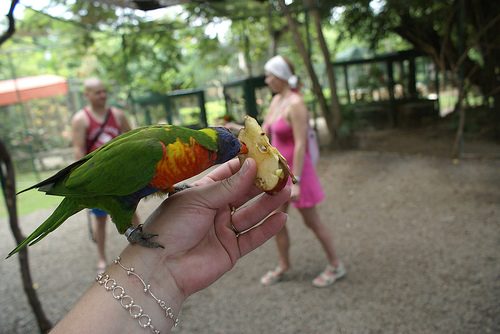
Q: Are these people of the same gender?
A: No, they are both male and female.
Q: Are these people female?
A: No, they are both male and female.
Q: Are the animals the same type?
A: No, they are birds and parrots.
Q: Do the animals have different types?
A: Yes, they are birds and parrots.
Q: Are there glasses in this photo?
A: No, there are no glasses.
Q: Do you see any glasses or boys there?
A: No, there are no glasses or boys.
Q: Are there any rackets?
A: No, there are no rackets.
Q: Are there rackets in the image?
A: No, there are no rackets.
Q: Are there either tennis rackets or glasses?
A: No, there are no tennis rackets or glasses.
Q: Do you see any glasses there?
A: No, there are no glasses.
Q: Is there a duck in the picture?
A: No, there are no ducks.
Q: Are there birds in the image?
A: Yes, there is a bird.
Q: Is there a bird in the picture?
A: Yes, there is a bird.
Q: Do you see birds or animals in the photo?
A: Yes, there is a bird.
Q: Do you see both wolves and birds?
A: No, there is a bird but no wolves.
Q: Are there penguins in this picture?
A: No, there are no penguins.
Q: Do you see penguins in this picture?
A: No, there are no penguins.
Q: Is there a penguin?
A: No, there are no penguins.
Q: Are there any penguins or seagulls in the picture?
A: No, there are no penguins or seagulls.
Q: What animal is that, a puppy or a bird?
A: That is a bird.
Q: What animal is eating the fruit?
A: The bird is eating the fruit.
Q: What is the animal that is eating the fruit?
A: The animal is a bird.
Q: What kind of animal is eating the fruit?
A: The animal is a bird.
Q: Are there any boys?
A: No, there are no boys.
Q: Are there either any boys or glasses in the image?
A: No, there are no boys or glasses.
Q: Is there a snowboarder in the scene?
A: No, there are no snowboarders.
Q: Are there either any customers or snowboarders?
A: No, there are no snowboarders or customers.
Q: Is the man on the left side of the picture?
A: Yes, the man is on the left of the image.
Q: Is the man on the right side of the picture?
A: No, the man is on the left of the image.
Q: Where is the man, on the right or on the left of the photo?
A: The man is on the left of the image.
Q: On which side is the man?
A: The man is on the left of the image.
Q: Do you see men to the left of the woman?
A: Yes, there is a man to the left of the woman.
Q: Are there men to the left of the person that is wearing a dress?
A: Yes, there is a man to the left of the woman.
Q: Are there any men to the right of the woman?
A: No, the man is to the left of the woman.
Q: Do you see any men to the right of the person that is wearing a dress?
A: No, the man is to the left of the woman.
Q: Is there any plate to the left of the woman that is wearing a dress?
A: No, there is a man to the left of the woman.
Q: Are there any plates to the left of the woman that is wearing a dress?
A: No, there is a man to the left of the woman.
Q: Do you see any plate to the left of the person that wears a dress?
A: No, there is a man to the left of the woman.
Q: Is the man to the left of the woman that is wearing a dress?
A: Yes, the man is to the left of the woman.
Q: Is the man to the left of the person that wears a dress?
A: Yes, the man is to the left of the woman.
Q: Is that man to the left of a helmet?
A: No, the man is to the left of the woman.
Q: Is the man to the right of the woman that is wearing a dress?
A: No, the man is to the left of the woman.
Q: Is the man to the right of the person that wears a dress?
A: No, the man is to the left of the woman.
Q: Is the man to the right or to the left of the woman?
A: The man is to the left of the woman.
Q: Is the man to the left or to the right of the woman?
A: The man is to the left of the woman.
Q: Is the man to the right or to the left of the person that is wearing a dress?
A: The man is to the left of the woman.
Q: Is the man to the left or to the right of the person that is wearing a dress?
A: The man is to the left of the woman.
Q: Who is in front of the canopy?
A: The man is in front of the canopy.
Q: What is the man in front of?
A: The man is in front of the canopy.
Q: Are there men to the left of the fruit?
A: Yes, there is a man to the left of the fruit.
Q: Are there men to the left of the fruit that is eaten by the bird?
A: Yes, there is a man to the left of the fruit.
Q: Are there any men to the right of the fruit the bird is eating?
A: No, the man is to the left of the fruit.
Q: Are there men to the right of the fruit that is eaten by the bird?
A: No, the man is to the left of the fruit.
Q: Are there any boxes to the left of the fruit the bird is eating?
A: No, there is a man to the left of the fruit.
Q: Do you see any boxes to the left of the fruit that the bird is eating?
A: No, there is a man to the left of the fruit.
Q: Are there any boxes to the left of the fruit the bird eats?
A: No, there is a man to the left of the fruit.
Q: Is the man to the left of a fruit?
A: Yes, the man is to the left of a fruit.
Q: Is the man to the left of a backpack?
A: No, the man is to the left of a fruit.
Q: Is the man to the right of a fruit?
A: No, the man is to the left of a fruit.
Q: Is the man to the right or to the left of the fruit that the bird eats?
A: The man is to the left of the fruit.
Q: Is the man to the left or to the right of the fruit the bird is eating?
A: The man is to the left of the fruit.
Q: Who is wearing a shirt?
A: The man is wearing a shirt.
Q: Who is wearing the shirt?
A: The man is wearing a shirt.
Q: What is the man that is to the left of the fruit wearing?
A: The man is wearing a shirt.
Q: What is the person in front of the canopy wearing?
A: The man is wearing a shirt.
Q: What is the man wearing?
A: The man is wearing a shirt.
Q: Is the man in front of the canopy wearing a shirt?
A: Yes, the man is wearing a shirt.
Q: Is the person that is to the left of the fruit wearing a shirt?
A: Yes, the man is wearing a shirt.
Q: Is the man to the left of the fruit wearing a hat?
A: No, the man is wearing a shirt.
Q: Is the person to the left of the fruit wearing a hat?
A: No, the man is wearing a shirt.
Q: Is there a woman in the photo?
A: Yes, there is a woman.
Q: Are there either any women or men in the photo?
A: Yes, there is a woman.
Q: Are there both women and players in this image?
A: No, there is a woman but no players.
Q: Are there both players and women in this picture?
A: No, there is a woman but no players.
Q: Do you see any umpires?
A: No, there are no umpires.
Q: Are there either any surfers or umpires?
A: No, there are no umpires or surfers.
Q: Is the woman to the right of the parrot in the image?
A: Yes, the woman is to the right of the parrot.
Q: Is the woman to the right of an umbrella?
A: No, the woman is to the right of the parrot.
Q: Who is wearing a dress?
A: The woman is wearing a dress.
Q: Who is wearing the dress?
A: The woman is wearing a dress.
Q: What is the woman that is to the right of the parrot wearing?
A: The woman is wearing a dress.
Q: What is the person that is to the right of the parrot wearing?
A: The woman is wearing a dress.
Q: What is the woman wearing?
A: The woman is wearing a dress.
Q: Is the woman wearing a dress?
A: Yes, the woman is wearing a dress.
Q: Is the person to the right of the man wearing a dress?
A: Yes, the woman is wearing a dress.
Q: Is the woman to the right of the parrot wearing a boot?
A: No, the woman is wearing a dress.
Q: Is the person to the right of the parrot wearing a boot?
A: No, the woman is wearing a dress.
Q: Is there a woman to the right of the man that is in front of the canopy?
A: Yes, there is a woman to the right of the man.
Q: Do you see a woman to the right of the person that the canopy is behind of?
A: Yes, there is a woman to the right of the man.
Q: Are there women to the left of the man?
A: No, the woman is to the right of the man.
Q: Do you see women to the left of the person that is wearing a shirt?
A: No, the woman is to the right of the man.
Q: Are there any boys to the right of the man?
A: No, there is a woman to the right of the man.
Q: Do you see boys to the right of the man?
A: No, there is a woman to the right of the man.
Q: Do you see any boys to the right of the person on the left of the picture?
A: No, there is a woman to the right of the man.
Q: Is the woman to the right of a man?
A: Yes, the woman is to the right of a man.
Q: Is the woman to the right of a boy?
A: No, the woman is to the right of a man.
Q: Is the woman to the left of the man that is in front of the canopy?
A: No, the woman is to the right of the man.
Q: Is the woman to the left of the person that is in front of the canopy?
A: No, the woman is to the right of the man.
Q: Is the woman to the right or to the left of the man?
A: The woman is to the right of the man.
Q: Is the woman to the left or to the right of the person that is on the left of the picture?
A: The woman is to the right of the man.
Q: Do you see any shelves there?
A: No, there are no shelves.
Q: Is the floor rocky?
A: Yes, the floor is rocky.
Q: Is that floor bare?
A: No, the floor is rocky.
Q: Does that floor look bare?
A: No, the floor is rocky.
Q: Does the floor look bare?
A: No, the floor is rocky.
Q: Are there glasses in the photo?
A: No, there are no glasses.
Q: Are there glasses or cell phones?
A: No, there are no glasses or cell phones.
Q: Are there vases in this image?
A: No, there are no vases.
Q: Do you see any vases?
A: No, there are no vases.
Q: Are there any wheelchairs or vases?
A: No, there are no vases or wheelchairs.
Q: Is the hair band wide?
A: Yes, the hair band is wide.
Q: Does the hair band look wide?
A: Yes, the hair band is wide.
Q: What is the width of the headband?
A: The headband is wide.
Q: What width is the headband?
A: The headband is wide.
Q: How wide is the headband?
A: The headband is wide.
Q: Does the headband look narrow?
A: No, the headband is wide.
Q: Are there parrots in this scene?
A: Yes, there is a parrot.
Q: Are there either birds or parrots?
A: Yes, there is a parrot.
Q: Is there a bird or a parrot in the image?
A: Yes, there is a parrot.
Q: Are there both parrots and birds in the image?
A: Yes, there are both a parrot and a bird.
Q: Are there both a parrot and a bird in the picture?
A: Yes, there are both a parrot and a bird.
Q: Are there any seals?
A: No, there are no seals.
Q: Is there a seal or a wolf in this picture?
A: No, there are no seals or wolves.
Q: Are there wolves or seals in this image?
A: No, there are no seals or wolves.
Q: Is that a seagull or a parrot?
A: That is a parrot.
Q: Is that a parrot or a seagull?
A: That is a parrot.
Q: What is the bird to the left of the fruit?
A: The bird is a parrot.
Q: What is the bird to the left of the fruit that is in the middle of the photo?
A: The bird is a parrot.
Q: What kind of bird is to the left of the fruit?
A: The bird is a parrot.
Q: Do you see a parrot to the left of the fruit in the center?
A: Yes, there is a parrot to the left of the fruit.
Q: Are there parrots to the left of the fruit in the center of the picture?
A: Yes, there is a parrot to the left of the fruit.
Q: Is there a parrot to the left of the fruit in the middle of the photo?
A: Yes, there is a parrot to the left of the fruit.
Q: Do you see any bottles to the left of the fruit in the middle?
A: No, there is a parrot to the left of the fruit.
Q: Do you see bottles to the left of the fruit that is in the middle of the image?
A: No, there is a parrot to the left of the fruit.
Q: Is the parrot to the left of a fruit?
A: Yes, the parrot is to the left of a fruit.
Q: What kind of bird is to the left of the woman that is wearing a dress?
A: The bird is a parrot.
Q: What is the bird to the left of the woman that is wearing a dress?
A: The bird is a parrot.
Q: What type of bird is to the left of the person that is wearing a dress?
A: The bird is a parrot.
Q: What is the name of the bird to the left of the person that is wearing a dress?
A: The bird is a parrot.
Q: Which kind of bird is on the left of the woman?
A: The bird is a parrot.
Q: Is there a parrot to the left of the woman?
A: Yes, there is a parrot to the left of the woman.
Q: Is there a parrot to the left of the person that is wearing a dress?
A: Yes, there is a parrot to the left of the woman.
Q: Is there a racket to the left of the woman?
A: No, there is a parrot to the left of the woman.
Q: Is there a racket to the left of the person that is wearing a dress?
A: No, there is a parrot to the left of the woman.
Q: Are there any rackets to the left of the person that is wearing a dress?
A: No, there is a parrot to the left of the woman.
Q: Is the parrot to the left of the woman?
A: Yes, the parrot is to the left of the woman.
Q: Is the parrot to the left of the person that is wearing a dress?
A: Yes, the parrot is to the left of the woman.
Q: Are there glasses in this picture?
A: No, there are no glasses.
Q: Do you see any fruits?
A: Yes, there is a fruit.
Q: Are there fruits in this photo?
A: Yes, there is a fruit.